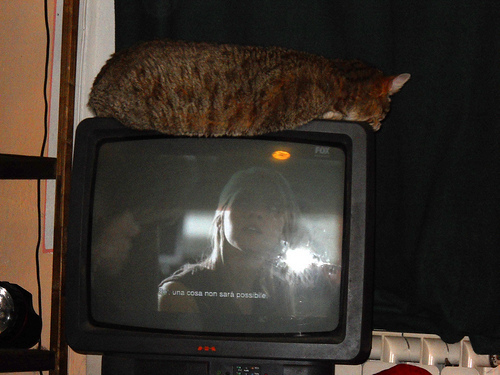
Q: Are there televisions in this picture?
A: Yes, there is a television.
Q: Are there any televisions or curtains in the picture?
A: Yes, there is a television.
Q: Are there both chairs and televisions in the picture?
A: No, there is a television but no chairs.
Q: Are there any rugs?
A: No, there are no rugs.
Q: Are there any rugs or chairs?
A: No, there are no rugs or chairs.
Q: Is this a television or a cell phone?
A: This is a television.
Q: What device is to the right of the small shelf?
A: The device is a television.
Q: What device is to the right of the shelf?
A: The device is a television.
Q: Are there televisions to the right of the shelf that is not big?
A: Yes, there is a television to the right of the shelf.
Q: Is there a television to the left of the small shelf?
A: No, the television is to the right of the shelf.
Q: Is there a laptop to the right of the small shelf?
A: No, there is a television to the right of the shelf.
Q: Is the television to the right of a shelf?
A: Yes, the television is to the right of a shelf.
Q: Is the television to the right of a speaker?
A: No, the television is to the right of a shelf.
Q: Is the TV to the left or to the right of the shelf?
A: The TV is to the right of the shelf.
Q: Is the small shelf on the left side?
A: Yes, the shelf is on the left of the image.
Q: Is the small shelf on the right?
A: No, the shelf is on the left of the image.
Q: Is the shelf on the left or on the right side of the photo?
A: The shelf is on the left of the image.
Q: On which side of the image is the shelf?
A: The shelf is on the left of the image.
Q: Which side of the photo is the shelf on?
A: The shelf is on the left of the image.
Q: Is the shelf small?
A: Yes, the shelf is small.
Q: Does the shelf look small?
A: Yes, the shelf is small.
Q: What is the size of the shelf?
A: The shelf is small.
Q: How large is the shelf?
A: The shelf is small.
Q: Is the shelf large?
A: No, the shelf is small.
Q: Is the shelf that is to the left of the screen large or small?
A: The shelf is small.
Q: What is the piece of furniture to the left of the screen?
A: The piece of furniture is a shelf.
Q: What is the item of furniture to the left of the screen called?
A: The piece of furniture is a shelf.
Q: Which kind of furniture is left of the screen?
A: The piece of furniture is a shelf.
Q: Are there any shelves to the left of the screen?
A: Yes, there is a shelf to the left of the screen.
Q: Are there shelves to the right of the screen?
A: No, the shelf is to the left of the screen.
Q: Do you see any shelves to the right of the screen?
A: No, the shelf is to the left of the screen.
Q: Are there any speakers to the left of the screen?
A: No, there is a shelf to the left of the screen.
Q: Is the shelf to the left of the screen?
A: Yes, the shelf is to the left of the screen.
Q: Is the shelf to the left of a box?
A: No, the shelf is to the left of the screen.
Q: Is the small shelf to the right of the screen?
A: No, the shelf is to the left of the screen.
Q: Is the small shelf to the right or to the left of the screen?
A: The shelf is to the left of the screen.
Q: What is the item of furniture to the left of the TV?
A: The piece of furniture is a shelf.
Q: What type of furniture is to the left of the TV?
A: The piece of furniture is a shelf.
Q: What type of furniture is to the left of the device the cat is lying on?
A: The piece of furniture is a shelf.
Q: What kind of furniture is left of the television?
A: The piece of furniture is a shelf.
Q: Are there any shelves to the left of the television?
A: Yes, there is a shelf to the left of the television.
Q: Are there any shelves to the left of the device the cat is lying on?
A: Yes, there is a shelf to the left of the television.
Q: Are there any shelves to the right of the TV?
A: No, the shelf is to the left of the TV.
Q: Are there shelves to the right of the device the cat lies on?
A: No, the shelf is to the left of the TV.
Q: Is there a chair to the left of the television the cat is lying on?
A: No, there is a shelf to the left of the television.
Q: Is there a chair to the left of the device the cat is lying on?
A: No, there is a shelf to the left of the television.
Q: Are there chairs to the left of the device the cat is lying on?
A: No, there is a shelf to the left of the television.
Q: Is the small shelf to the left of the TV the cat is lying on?
A: Yes, the shelf is to the left of the TV.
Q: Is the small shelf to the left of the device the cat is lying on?
A: Yes, the shelf is to the left of the TV.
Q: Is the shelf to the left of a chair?
A: No, the shelf is to the left of the TV.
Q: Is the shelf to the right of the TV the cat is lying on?
A: No, the shelf is to the left of the TV.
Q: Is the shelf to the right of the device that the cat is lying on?
A: No, the shelf is to the left of the TV.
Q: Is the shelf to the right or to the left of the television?
A: The shelf is to the left of the television.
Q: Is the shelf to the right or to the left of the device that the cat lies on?
A: The shelf is to the left of the television.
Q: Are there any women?
A: Yes, there is a woman.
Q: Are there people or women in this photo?
A: Yes, there is a woman.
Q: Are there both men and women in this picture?
A: No, there is a woman but no men.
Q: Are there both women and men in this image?
A: No, there is a woman but no men.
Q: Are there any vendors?
A: No, there are no vendors.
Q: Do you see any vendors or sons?
A: No, there are no vendors or sons.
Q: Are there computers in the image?
A: No, there are no computers.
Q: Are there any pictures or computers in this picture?
A: No, there are no computers or pictures.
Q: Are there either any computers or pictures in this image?
A: No, there are no computers or pictures.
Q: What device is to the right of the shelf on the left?
A: The device is a screen.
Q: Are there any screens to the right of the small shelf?
A: Yes, there is a screen to the right of the shelf.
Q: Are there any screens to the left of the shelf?
A: No, the screen is to the right of the shelf.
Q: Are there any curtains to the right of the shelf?
A: No, there is a screen to the right of the shelf.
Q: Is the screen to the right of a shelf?
A: Yes, the screen is to the right of a shelf.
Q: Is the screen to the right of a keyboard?
A: No, the screen is to the right of a shelf.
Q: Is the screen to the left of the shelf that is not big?
A: No, the screen is to the right of the shelf.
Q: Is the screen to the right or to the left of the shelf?
A: The screen is to the right of the shelf.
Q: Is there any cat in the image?
A: Yes, there is a cat.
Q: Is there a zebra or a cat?
A: Yes, there is a cat.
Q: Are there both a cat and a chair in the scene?
A: No, there is a cat but no chairs.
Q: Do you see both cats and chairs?
A: No, there is a cat but no chairs.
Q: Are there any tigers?
A: No, there are no tigers.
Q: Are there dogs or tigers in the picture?
A: No, there are no tigers or dogs.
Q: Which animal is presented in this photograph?
A: The animal is a cat.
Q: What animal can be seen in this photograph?
A: The animal is a cat.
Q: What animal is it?
A: The animal is a cat.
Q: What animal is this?
A: This is a cat.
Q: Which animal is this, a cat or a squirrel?
A: This is a cat.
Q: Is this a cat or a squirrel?
A: This is a cat.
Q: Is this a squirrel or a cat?
A: This is a cat.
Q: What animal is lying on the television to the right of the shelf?
A: The cat is lying on the television.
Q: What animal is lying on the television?
A: The cat is lying on the television.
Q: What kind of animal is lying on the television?
A: The animal is a cat.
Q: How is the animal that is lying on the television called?
A: The animal is a cat.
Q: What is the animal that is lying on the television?
A: The animal is a cat.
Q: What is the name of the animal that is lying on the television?
A: The animal is a cat.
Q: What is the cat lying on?
A: The cat is lying on the television.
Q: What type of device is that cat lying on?
A: The cat is lying on the television.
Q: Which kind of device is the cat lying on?
A: The cat is lying on the television.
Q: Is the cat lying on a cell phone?
A: No, the cat is lying on the television.